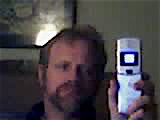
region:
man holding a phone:
[13, 16, 152, 119]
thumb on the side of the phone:
[107, 74, 123, 109]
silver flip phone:
[116, 39, 144, 116]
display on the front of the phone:
[120, 51, 139, 64]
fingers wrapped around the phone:
[125, 72, 158, 119]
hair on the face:
[43, 75, 99, 112]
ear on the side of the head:
[36, 62, 49, 91]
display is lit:
[122, 54, 137, 63]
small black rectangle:
[125, 67, 135, 74]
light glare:
[32, 26, 60, 47]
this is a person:
[27, 23, 157, 118]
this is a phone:
[109, 28, 145, 116]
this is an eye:
[59, 61, 68, 73]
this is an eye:
[77, 60, 90, 82]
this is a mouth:
[59, 83, 80, 102]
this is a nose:
[67, 74, 79, 84]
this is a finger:
[103, 73, 119, 112]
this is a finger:
[129, 107, 147, 119]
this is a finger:
[126, 94, 156, 113]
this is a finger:
[135, 77, 156, 98]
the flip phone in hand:
[115, 35, 143, 111]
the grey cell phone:
[115, 36, 145, 111]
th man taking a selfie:
[23, 22, 153, 119]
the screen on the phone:
[118, 50, 137, 65]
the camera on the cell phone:
[125, 69, 132, 74]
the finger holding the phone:
[132, 78, 156, 91]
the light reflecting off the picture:
[29, 0, 57, 46]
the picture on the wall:
[0, 0, 35, 50]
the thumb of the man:
[106, 76, 119, 114]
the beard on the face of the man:
[41, 80, 98, 109]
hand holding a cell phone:
[107, 28, 156, 118]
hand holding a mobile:
[106, 30, 156, 119]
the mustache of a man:
[50, 77, 96, 102]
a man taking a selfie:
[9, 7, 158, 119]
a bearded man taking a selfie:
[22, 18, 158, 117]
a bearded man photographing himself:
[17, 15, 157, 119]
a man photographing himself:
[16, 17, 159, 119]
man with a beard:
[27, 17, 107, 119]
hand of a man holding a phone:
[106, 31, 158, 119]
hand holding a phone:
[101, 21, 156, 119]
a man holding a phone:
[15, 16, 157, 119]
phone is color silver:
[114, 33, 144, 117]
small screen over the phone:
[122, 52, 135, 63]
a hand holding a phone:
[104, 35, 157, 119]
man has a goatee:
[10, 20, 158, 118]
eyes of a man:
[54, 60, 91, 76]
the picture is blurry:
[1, 1, 157, 119]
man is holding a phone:
[0, 17, 159, 118]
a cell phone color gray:
[113, 32, 145, 115]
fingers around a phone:
[106, 34, 155, 119]